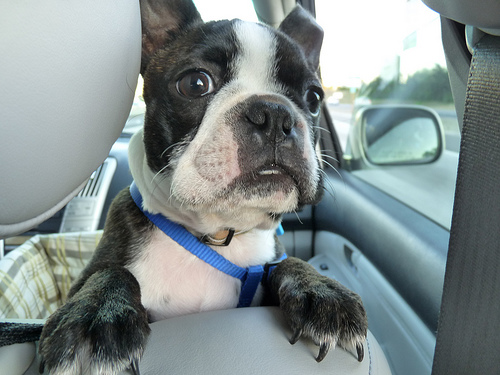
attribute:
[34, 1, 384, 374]
dog — cuddly, curious, alert, nice, adorable, friendly, cute, white, black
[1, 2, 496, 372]
vehicle — grey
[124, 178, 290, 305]
leash — blue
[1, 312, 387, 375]
seat — white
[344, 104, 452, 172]
mirror — white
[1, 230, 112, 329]
basket — plaid, checked, yellow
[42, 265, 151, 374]
leg — black, long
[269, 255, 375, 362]
leg — black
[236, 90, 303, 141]
nose — black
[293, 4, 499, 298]
side — gray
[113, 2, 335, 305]
head — white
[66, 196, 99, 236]
control — white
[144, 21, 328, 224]
face — white, black